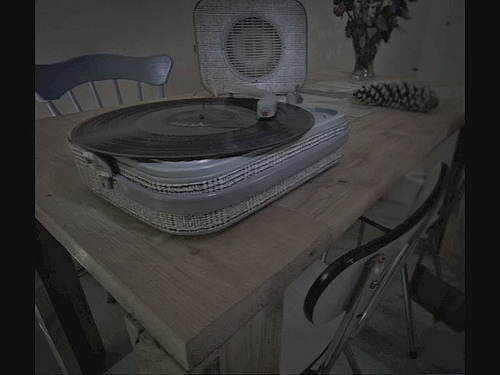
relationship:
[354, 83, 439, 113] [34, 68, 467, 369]
cone sitting on table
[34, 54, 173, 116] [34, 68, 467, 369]
chair underneath table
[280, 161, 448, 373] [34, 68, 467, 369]
chair underneath table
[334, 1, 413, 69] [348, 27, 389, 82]
plants displayed in vase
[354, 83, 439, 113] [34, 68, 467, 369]
cone lying on table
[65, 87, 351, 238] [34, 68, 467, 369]
record player sitting on table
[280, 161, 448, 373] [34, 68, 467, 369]
chair sitting at table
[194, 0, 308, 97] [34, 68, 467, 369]
fan sitting on table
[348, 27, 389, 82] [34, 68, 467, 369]
vase sitting on table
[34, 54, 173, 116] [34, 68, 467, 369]
chair sitting at table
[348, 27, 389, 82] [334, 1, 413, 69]
vase of plants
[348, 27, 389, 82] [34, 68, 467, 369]
vase sitting at table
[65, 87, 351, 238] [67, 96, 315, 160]
record player with record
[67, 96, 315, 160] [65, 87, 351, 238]
record sitting on record player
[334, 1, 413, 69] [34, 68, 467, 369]
plants sitting on table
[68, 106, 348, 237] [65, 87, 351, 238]
lining around record player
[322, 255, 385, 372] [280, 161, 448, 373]
metal piece in back of chair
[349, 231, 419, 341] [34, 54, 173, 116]
metal piece in back of chair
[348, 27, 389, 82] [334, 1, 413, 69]
vase with plants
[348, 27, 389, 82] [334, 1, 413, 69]
vase for plants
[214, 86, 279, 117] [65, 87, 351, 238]
arm of record player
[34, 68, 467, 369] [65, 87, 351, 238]
table beneath record player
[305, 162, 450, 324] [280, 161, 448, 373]
trim of chair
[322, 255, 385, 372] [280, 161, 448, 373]
metal piece of chair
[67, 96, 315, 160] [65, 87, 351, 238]
record on top of record player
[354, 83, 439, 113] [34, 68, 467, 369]
cone on top of table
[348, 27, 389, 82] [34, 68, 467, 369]
vase in corner of table